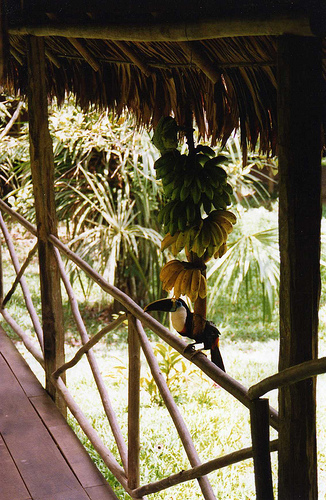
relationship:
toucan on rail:
[144, 298, 227, 375] [2, 185, 321, 470]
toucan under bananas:
[140, 294, 228, 375] [155, 255, 212, 306]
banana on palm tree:
[186, 181, 203, 209] [207, 206, 279, 321]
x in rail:
[46, 249, 127, 464] [0, 199, 278, 433]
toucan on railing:
[144, 298, 227, 375] [79, 320, 249, 368]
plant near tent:
[205, 130, 275, 202] [6, 6, 324, 492]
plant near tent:
[53, 163, 165, 300] [6, 6, 324, 492]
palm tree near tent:
[207, 206, 279, 321] [6, 6, 324, 492]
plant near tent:
[7, 98, 116, 217] [6, 6, 324, 492]